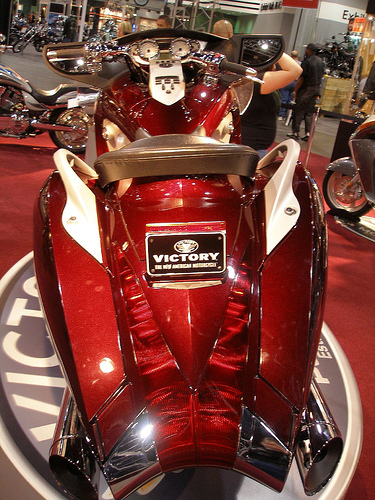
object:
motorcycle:
[34, 19, 329, 480]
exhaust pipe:
[298, 418, 343, 499]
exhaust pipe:
[43, 405, 102, 495]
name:
[151, 252, 223, 270]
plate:
[145, 222, 231, 285]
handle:
[220, 55, 264, 88]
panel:
[130, 36, 208, 65]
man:
[213, 15, 241, 42]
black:
[292, 118, 300, 126]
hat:
[303, 42, 324, 53]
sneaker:
[290, 134, 298, 142]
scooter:
[3, 68, 91, 153]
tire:
[52, 111, 87, 153]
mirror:
[41, 41, 94, 73]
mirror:
[240, 31, 287, 69]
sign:
[322, 2, 364, 23]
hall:
[21, 4, 358, 58]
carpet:
[4, 155, 36, 240]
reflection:
[128, 187, 228, 213]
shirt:
[304, 59, 320, 87]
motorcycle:
[12, 27, 49, 52]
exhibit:
[6, 288, 61, 413]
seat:
[113, 136, 245, 173]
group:
[11, 13, 33, 35]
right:
[317, 130, 339, 174]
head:
[211, 19, 234, 38]